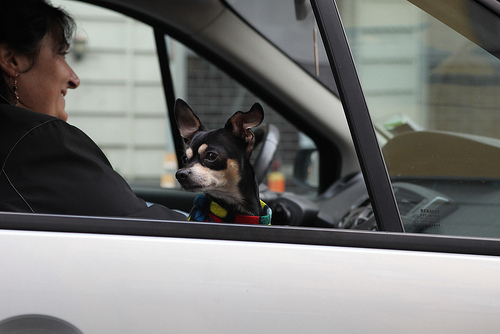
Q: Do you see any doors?
A: Yes, there is a door.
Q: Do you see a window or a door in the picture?
A: Yes, there is a door.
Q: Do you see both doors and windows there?
A: Yes, there are both a door and a window.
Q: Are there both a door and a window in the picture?
A: Yes, there are both a door and a window.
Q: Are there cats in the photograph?
A: No, there are no cats.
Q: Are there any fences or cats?
A: No, there are no cats or fences.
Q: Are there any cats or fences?
A: No, there are no cats or fences.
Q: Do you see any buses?
A: No, there are no buses.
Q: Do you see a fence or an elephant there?
A: No, there are no fences or elephants.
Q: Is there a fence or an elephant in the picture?
A: No, there are no fences or elephants.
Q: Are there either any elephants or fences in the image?
A: No, there are no fences or elephants.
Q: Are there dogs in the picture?
A: Yes, there is a dog.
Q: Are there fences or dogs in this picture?
A: Yes, there is a dog.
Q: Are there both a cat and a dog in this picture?
A: No, there is a dog but no cats.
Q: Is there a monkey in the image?
A: No, there are no monkeys.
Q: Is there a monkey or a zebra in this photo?
A: No, there are no monkeys or zebras.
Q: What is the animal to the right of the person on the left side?
A: The animal is a dog.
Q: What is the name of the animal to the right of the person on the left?
A: The animal is a dog.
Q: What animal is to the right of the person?
A: The animal is a dog.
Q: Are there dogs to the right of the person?
A: Yes, there is a dog to the right of the person.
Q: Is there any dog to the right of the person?
A: Yes, there is a dog to the right of the person.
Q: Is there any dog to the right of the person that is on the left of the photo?
A: Yes, there is a dog to the right of the person.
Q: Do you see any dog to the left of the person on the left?
A: No, the dog is to the right of the person.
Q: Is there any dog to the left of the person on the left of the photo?
A: No, the dog is to the right of the person.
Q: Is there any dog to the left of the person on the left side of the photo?
A: No, the dog is to the right of the person.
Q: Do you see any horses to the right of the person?
A: No, there is a dog to the right of the person.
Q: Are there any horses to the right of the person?
A: No, there is a dog to the right of the person.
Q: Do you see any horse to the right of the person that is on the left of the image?
A: No, there is a dog to the right of the person.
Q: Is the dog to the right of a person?
A: Yes, the dog is to the right of a person.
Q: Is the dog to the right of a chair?
A: No, the dog is to the right of a person.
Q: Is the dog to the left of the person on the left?
A: No, the dog is to the right of the person.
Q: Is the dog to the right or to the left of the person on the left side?
A: The dog is to the right of the person.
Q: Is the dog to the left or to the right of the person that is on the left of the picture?
A: The dog is to the right of the person.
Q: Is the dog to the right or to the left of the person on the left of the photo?
A: The dog is to the right of the person.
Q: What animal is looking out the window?
A: The dog is looking out the window.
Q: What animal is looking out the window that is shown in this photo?
A: The animal is a dog.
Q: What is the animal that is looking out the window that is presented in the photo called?
A: The animal is a dog.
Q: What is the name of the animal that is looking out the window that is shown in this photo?
A: The animal is a dog.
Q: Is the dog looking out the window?
A: Yes, the dog is looking out the window.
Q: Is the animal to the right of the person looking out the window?
A: Yes, the dog is looking out the window.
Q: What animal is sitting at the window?
A: The dog is sitting at the window.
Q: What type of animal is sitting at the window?
A: The animal is a dog.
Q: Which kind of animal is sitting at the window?
A: The animal is a dog.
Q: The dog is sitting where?
A: The dog is sitting at the window.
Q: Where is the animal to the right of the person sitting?
A: The dog is sitting at the window.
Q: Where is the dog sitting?
A: The dog is sitting at the window.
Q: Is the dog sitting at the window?
A: Yes, the dog is sitting at the window.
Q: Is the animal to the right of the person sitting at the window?
A: Yes, the dog is sitting at the window.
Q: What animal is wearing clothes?
A: The animal is a dog.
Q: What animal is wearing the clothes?
A: The animal is a dog.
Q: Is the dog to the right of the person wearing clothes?
A: Yes, the dog is wearing clothes.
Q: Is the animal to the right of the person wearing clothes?
A: Yes, the dog is wearing clothes.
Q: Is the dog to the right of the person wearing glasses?
A: No, the dog is wearing clothes.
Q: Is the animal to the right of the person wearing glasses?
A: No, the dog is wearing clothes.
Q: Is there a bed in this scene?
A: No, there are no beds.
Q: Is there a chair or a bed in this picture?
A: No, there are no beds or chairs.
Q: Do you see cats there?
A: No, there are no cats.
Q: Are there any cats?
A: No, there are no cats.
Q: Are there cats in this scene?
A: No, there are no cats.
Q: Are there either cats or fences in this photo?
A: No, there are no cats or fences.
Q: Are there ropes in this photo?
A: No, there are no ropes.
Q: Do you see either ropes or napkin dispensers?
A: No, there are no ropes or napkin dispensers.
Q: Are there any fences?
A: No, there are no fences.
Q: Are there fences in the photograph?
A: No, there are no fences.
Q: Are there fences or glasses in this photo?
A: No, there are no fences or glasses.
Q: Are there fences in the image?
A: No, there are no fences.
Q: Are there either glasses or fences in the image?
A: No, there are no fences or glasses.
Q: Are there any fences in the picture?
A: No, there are no fences.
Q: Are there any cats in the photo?
A: No, there are no cats.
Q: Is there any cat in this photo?
A: No, there are no cats.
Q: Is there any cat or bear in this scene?
A: No, there are no cats or bears.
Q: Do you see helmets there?
A: No, there are no helmets.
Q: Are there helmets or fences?
A: No, there are no helmets or fences.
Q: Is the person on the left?
A: Yes, the person is on the left of the image.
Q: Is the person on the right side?
A: No, the person is on the left of the image.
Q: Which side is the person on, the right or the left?
A: The person is on the left of the image.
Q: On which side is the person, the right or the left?
A: The person is on the left of the image.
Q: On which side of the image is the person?
A: The person is on the left of the image.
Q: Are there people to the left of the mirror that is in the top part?
A: Yes, there is a person to the left of the mirror.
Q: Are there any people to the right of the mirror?
A: No, the person is to the left of the mirror.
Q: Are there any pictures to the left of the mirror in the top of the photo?
A: No, there is a person to the left of the mirror.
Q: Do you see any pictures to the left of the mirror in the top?
A: No, there is a person to the left of the mirror.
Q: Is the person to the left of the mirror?
A: Yes, the person is to the left of the mirror.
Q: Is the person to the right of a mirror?
A: No, the person is to the left of a mirror.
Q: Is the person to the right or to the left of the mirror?
A: The person is to the left of the mirror.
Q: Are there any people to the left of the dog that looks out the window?
A: Yes, there is a person to the left of the dog.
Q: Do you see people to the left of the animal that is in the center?
A: Yes, there is a person to the left of the dog.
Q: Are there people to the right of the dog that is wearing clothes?
A: No, the person is to the left of the dog.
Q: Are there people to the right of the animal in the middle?
A: No, the person is to the left of the dog.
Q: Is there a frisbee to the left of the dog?
A: No, there is a person to the left of the dog.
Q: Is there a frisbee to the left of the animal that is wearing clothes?
A: No, there is a person to the left of the dog.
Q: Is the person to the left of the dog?
A: Yes, the person is to the left of the dog.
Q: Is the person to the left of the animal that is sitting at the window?
A: Yes, the person is to the left of the dog.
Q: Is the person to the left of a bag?
A: No, the person is to the left of the dog.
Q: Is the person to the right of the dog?
A: No, the person is to the left of the dog.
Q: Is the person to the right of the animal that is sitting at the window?
A: No, the person is to the left of the dog.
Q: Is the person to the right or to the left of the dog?
A: The person is to the left of the dog.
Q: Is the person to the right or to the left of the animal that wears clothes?
A: The person is to the left of the dog.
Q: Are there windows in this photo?
A: Yes, there is a window.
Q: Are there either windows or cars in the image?
A: Yes, there is a window.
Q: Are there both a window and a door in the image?
A: Yes, there are both a window and a door.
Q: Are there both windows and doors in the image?
A: Yes, there are both a window and a door.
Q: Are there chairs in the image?
A: No, there are no chairs.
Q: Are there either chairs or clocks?
A: No, there are no chairs or clocks.